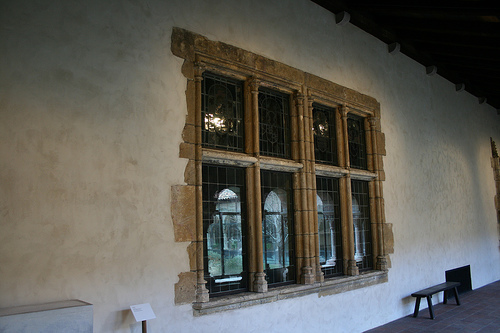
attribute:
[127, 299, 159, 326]
plaque — little 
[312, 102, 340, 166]
window — small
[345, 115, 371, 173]
window — small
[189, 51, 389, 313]
trim — brown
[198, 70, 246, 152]
window — small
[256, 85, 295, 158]
window — small